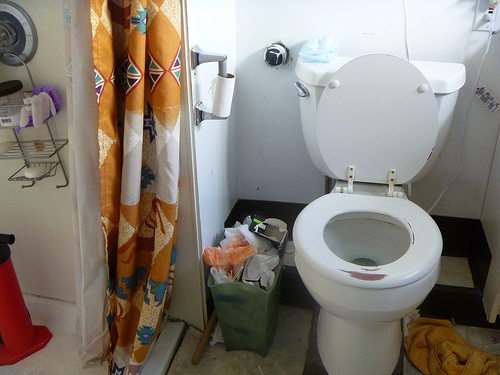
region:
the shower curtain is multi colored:
[95, 89, 179, 367]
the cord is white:
[474, 30, 495, 66]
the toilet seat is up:
[312, 41, 441, 193]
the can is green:
[212, 277, 282, 354]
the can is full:
[200, 207, 287, 358]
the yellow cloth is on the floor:
[407, 315, 499, 370]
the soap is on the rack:
[12, 160, 49, 179]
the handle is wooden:
[185, 323, 210, 363]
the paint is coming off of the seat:
[339, 260, 394, 287]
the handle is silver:
[284, 77, 311, 100]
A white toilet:
[251, 33, 478, 373]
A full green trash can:
[204, 205, 286, 355]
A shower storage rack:
[0, 53, 73, 193]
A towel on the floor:
[398, 310, 499, 372]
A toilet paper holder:
[191, 45, 241, 132]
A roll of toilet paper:
[207, 70, 242, 120]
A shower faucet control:
[0, 3, 37, 63]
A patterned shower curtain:
[81, 1, 188, 371]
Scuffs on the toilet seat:
[327, 256, 402, 290]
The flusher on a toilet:
[290, 77, 319, 103]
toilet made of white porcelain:
[266, 41, 485, 374]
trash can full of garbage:
[200, 209, 306, 369]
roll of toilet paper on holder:
[186, 45, 248, 130]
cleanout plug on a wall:
[260, 38, 293, 73]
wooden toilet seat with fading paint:
[291, 186, 447, 290]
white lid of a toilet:
[307, 54, 449, 200]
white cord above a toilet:
[392, 0, 422, 68]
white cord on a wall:
[416, 11, 498, 218]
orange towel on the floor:
[396, 306, 498, 373]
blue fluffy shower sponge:
[292, 31, 349, 73]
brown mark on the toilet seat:
[346, 266, 387, 284]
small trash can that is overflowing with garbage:
[201, 216, 283, 358]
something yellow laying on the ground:
[400, 310, 492, 374]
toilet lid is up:
[312, 51, 446, 191]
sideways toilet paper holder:
[192, 38, 246, 131]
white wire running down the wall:
[425, 9, 499, 205]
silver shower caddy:
[1, 20, 77, 197]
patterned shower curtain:
[77, 2, 197, 373]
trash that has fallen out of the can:
[208, 321, 223, 346]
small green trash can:
[207, 257, 295, 360]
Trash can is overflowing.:
[180, 195, 286, 366]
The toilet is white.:
[280, 27, 442, 368]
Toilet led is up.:
[285, 32, 465, 369]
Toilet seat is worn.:
[286, 45, 451, 305]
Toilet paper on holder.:
[185, 25, 255, 140]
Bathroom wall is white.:
[185, 0, 498, 320]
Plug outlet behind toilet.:
[468, 1, 498, 35]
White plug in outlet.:
[461, 2, 498, 42]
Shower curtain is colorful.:
[71, 2, 196, 374]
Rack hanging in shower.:
[1, 50, 79, 209]